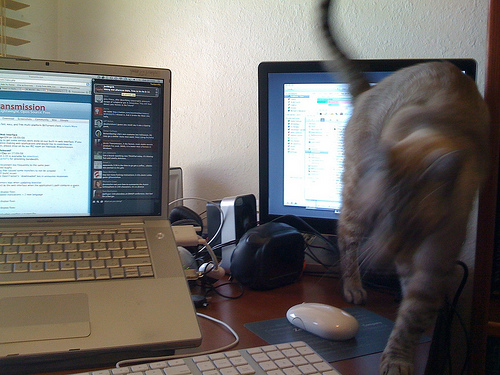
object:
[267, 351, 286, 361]
key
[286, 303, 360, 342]
computer mouse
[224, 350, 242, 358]
key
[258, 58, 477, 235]
computer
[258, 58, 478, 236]
computer monitor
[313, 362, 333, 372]
key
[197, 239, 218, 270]
cable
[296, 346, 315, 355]
key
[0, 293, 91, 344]
trackpad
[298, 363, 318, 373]
white key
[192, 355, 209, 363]
key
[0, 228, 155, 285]
key board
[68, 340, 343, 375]
keyboard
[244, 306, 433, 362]
mousepad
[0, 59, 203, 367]
computer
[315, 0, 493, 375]
cat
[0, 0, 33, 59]
blinds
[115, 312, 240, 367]
cord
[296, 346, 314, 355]
key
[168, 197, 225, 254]
wires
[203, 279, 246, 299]
cords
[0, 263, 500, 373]
desk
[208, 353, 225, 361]
key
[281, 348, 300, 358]
key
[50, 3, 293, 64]
wall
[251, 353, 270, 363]
key